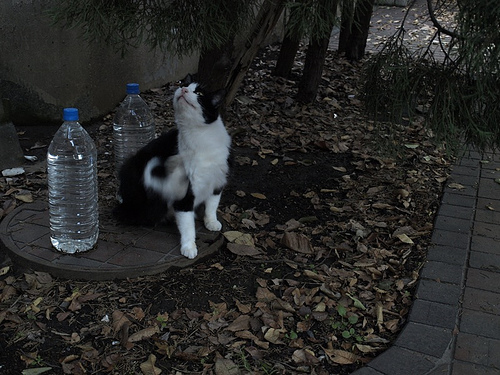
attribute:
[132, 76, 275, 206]
cat — black, white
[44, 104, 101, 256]
water bottle — clear, plastic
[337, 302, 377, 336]
grass — green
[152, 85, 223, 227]
cat — black and white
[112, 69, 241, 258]
cat — small, black, white, furry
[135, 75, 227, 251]
cat — furry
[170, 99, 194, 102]
nose — pink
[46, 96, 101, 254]
bottle — large, plastic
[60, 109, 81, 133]
cap — blue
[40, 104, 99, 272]
water bottle — tall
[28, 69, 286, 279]
brick — circular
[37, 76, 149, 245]
bottle — tall, plastic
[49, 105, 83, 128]
cap — blue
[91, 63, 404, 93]
trees — green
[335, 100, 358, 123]
trunks — brown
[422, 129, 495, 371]
cobblestone — gray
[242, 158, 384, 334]
dirt — black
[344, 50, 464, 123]
branches — green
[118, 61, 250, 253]
cat — black, white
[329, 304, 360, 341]
plant — green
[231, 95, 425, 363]
leaves — brown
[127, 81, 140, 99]
top — blue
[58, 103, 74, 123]
top — blue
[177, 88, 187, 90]
nose — pink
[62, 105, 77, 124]
cap — blue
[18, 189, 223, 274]
object — round